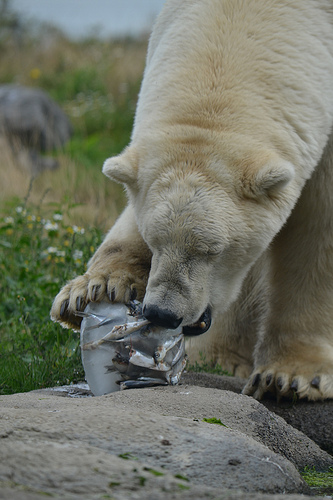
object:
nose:
[142, 303, 181, 329]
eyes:
[203, 241, 222, 262]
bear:
[46, 0, 332, 405]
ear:
[100, 152, 137, 187]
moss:
[203, 413, 226, 429]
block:
[79, 296, 189, 398]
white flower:
[40, 217, 45, 224]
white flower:
[73, 223, 85, 235]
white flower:
[73, 248, 84, 261]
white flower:
[44, 220, 57, 231]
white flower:
[47, 244, 57, 252]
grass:
[0, 340, 32, 393]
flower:
[19, 56, 50, 93]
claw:
[49, 267, 145, 335]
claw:
[239, 354, 331, 401]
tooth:
[200, 321, 206, 329]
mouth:
[176, 298, 212, 338]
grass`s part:
[35, 358, 64, 384]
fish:
[82, 297, 184, 389]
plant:
[305, 471, 315, 492]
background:
[17, 4, 125, 143]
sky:
[0, 0, 166, 43]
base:
[80, 300, 186, 397]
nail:
[57, 297, 68, 318]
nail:
[74, 294, 81, 311]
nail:
[107, 288, 117, 301]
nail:
[107, 286, 116, 301]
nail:
[75, 294, 83, 312]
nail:
[249, 370, 259, 386]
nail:
[266, 373, 272, 386]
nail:
[289, 379, 300, 393]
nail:
[277, 377, 285, 389]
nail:
[310, 375, 320, 388]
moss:
[139, 461, 162, 476]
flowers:
[43, 213, 84, 270]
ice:
[74, 287, 193, 404]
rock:
[0, 379, 333, 500]